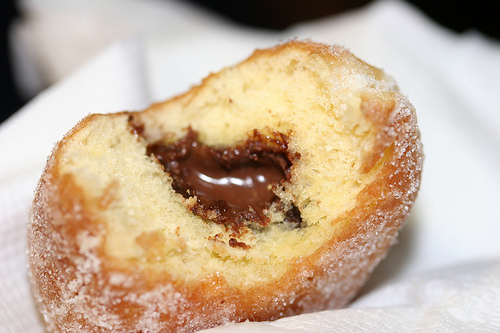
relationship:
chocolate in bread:
[140, 127, 294, 227] [22, 33, 423, 330]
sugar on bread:
[378, 119, 424, 242] [22, 33, 423, 330]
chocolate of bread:
[140, 127, 294, 227] [22, 33, 423, 330]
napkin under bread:
[3, 1, 499, 330] [22, 33, 423, 330]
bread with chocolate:
[22, 33, 423, 330] [139, 118, 308, 232]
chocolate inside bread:
[140, 127, 294, 227] [22, 33, 422, 333]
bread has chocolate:
[22, 33, 422, 333] [140, 127, 294, 227]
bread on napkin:
[22, 33, 422, 333] [3, 1, 499, 330]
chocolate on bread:
[140, 127, 294, 227] [22, 33, 422, 333]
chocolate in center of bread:
[140, 127, 294, 227] [22, 33, 422, 333]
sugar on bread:
[25, 175, 239, 332] [22, 33, 422, 333]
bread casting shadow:
[22, 33, 422, 333] [348, 215, 418, 305]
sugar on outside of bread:
[25, 175, 239, 332] [22, 33, 422, 333]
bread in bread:
[22, 33, 422, 333] [22, 33, 422, 333]